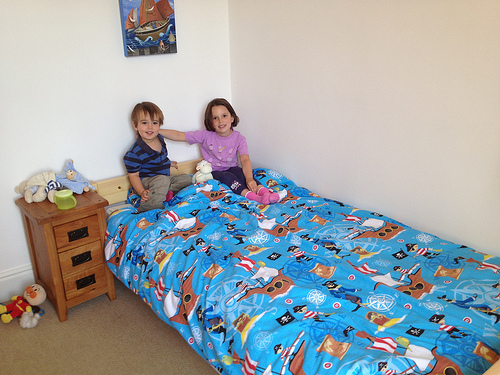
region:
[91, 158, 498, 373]
Twin bed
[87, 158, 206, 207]
Wooden bed head behind the children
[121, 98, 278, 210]
Couple of kids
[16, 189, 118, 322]
Small dresser next to the bed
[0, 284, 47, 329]
Stuffed duck on the ground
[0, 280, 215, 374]
Ground made of capet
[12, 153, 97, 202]
Stuffed animals on the dresser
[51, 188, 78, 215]
Green tea cup on the dresser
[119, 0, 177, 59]
Photo on the wall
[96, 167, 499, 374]
Bed cover with several animals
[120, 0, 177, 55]
a picture on the wall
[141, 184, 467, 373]
a blue bed spread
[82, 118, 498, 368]
a bed in a room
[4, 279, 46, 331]
a stuffed animal on the floor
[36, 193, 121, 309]
a little wooden dresser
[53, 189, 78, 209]
a cup on the dresser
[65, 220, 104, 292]
drawers of the dresser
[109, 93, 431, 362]
two kids sitting on a bed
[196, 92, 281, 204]
a kid in a purple shirt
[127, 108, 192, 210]
a kid in a striped blue shirt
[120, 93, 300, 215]
boy and girl sitting on a bed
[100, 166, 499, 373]
bed has blanket with pirate cartoons on it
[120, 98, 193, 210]
boy is wearing a black and blue striped polo shirt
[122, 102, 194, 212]
boy is wearing khaki pants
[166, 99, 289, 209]
girl is wearing a light purple shirt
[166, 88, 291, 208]
girl is wearing dark purple pants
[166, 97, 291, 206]
girl is waering pink socks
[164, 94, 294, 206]
girl has brown hair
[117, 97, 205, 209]
boy has light brown hair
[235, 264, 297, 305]
design on the comforter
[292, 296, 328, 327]
design on the comforter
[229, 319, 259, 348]
design on the comforter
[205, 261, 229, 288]
design on the comforter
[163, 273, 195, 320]
design on the comforter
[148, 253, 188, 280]
design on the comforter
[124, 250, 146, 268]
design on the comforter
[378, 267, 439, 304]
design on the comforter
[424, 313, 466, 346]
design on the comforter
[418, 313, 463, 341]
design on the comforter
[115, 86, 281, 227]
little boy and girl in a bed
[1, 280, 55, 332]
stuff snowman on the floor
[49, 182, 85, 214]
green cup on the table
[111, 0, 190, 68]
blue photo on the wall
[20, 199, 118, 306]
brown nightstand on the floor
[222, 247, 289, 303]
ship on the bed spread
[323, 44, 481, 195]
white wall behind the bed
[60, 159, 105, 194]
dolls on the nightstand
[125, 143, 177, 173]
blue and black striped shirt on boy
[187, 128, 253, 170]
purple shirt on the girl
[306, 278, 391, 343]
pirates design printed on cloth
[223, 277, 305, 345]
pirates design printed on cloth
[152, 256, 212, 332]
pirates design printed on cloth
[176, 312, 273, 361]
pirates design printed on cloth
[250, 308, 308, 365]
pirates design printed on cloth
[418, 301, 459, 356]
pirates design printed on cloth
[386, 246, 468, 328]
pirates design printed on cloth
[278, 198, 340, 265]
pirates design printed on cloth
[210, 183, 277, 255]
pirates design printed on cloth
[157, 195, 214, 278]
pirates design printed on cloth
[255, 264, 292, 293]
a boat on the blanket